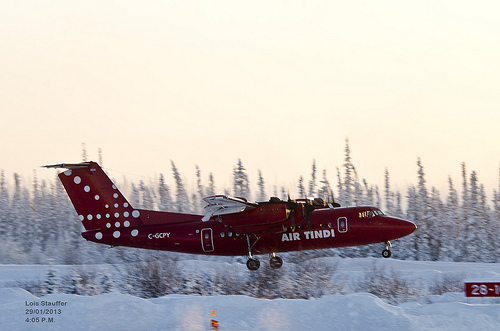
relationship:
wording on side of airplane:
[281, 231, 337, 240] [42, 162, 417, 269]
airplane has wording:
[42, 162, 417, 269] [281, 231, 337, 240]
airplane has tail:
[42, 162, 417, 269] [43, 162, 157, 230]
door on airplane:
[200, 229, 212, 253] [42, 162, 417, 269]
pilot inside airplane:
[366, 211, 373, 221] [42, 162, 417, 269]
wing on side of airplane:
[205, 192, 300, 227] [42, 162, 417, 269]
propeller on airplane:
[279, 190, 299, 228] [42, 162, 417, 269]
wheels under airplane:
[247, 255, 258, 272] [42, 162, 417, 269]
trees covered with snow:
[413, 157, 500, 257] [11, 287, 500, 330]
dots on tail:
[103, 208, 130, 229] [43, 162, 157, 230]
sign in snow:
[463, 283, 500, 308] [11, 287, 500, 330]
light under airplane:
[295, 245, 298, 252] [42, 162, 417, 269]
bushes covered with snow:
[135, 253, 328, 304] [11, 287, 500, 330]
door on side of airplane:
[200, 229, 212, 253] [42, 162, 417, 269]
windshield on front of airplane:
[375, 208, 382, 215] [42, 162, 417, 269]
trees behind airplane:
[413, 157, 500, 257] [42, 162, 417, 269]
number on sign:
[471, 285, 489, 297] [463, 283, 500, 308]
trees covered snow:
[413, 157, 500, 257] [11, 287, 500, 330]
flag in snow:
[208, 322, 215, 328] [11, 287, 500, 330]